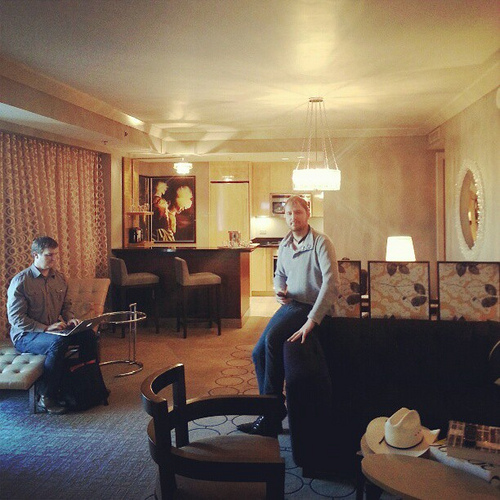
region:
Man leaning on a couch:
[234, 191, 338, 434]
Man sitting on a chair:
[6, 235, 82, 412]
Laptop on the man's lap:
[43, 310, 112, 337]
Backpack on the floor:
[46, 327, 110, 416]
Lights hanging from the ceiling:
[172, 96, 340, 192]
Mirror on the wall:
[452, 156, 484, 261]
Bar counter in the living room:
[112, 245, 258, 329]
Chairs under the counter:
[107, 255, 222, 337]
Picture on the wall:
[135, 173, 197, 243]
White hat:
[365, 406, 440, 457]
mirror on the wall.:
[461, 173, 472, 231]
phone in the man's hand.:
[270, 288, 292, 305]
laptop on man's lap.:
[64, 313, 99, 345]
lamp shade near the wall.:
[382, 233, 411, 258]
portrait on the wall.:
[159, 185, 191, 231]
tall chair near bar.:
[175, 260, 227, 323]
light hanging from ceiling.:
[286, 165, 338, 185]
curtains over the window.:
[16, 171, 81, 216]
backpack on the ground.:
[63, 341, 92, 398]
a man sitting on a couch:
[217, 118, 387, 458]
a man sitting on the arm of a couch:
[208, 120, 410, 487]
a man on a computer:
[0, 186, 162, 486]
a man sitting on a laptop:
[12, 189, 159, 444]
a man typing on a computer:
[18, 208, 173, 458]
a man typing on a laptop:
[15, 215, 124, 432]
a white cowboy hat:
[362, 372, 464, 498]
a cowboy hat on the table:
[334, 378, 491, 499]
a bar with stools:
[100, 165, 297, 362]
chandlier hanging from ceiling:
[278, 83, 357, 212]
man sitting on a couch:
[256, 193, 339, 381]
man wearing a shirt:
[245, 188, 335, 368]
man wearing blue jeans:
[240, 166, 335, 377]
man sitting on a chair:
[0, 225, 107, 416]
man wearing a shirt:
[0, 231, 120, 426]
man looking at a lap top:
[6, 213, 116, 400]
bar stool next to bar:
[157, 241, 237, 346]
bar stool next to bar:
[106, 246, 159, 291]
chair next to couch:
[141, 305, 282, 496]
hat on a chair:
[365, 402, 427, 474]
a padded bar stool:
[107, 255, 164, 332]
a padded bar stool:
[170, 253, 221, 339]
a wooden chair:
[140, 360, 287, 493]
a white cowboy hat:
[366, 405, 438, 461]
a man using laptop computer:
[5, 237, 107, 415]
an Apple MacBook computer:
[43, 313, 104, 336]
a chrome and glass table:
[98, 305, 145, 379]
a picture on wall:
[148, 175, 195, 243]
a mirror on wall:
[455, 160, 484, 261]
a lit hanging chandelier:
[288, 97, 340, 192]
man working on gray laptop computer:
[51, 316, 109, 338]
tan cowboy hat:
[368, 395, 443, 462]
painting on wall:
[146, 173, 207, 244]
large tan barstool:
[168, 253, 230, 330]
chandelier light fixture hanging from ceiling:
[288, 94, 344, 196]